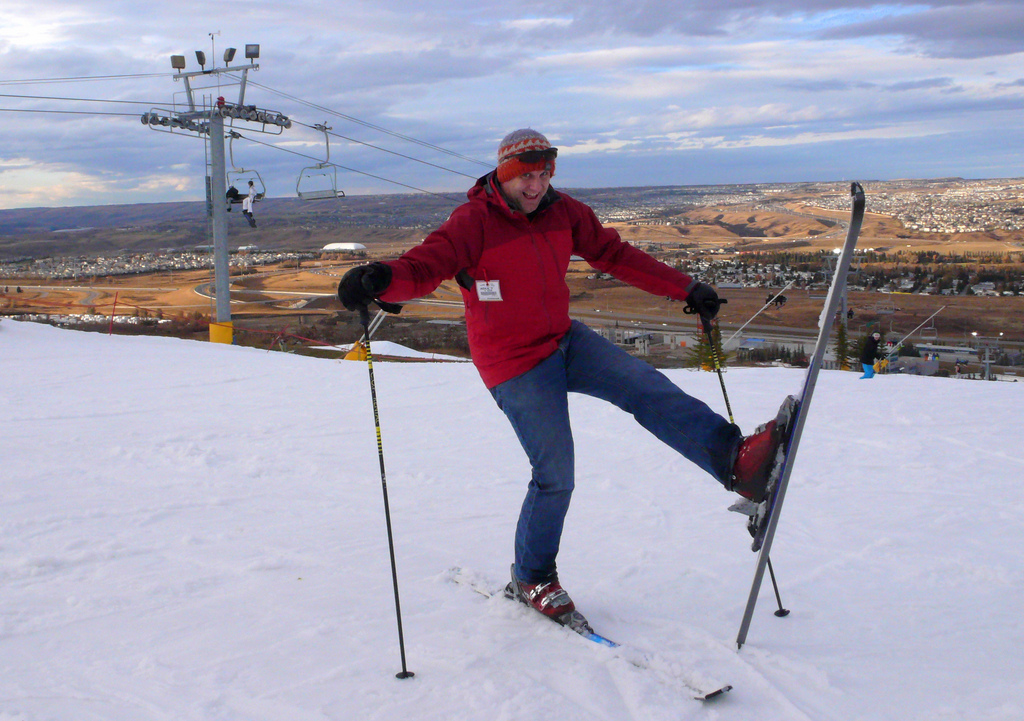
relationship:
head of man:
[394, 112, 590, 272] [394, 112, 590, 272]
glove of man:
[340, 254, 392, 309] [340, 124, 734, 631]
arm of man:
[566, 193, 702, 301] [686, 278, 725, 323]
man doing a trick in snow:
[332, 118, 803, 625] [6, 362, 1022, 717]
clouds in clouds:
[0, 0, 1024, 209] [0, 0, 1024, 209]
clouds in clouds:
[574, 71, 729, 114] [0, 0, 1024, 209]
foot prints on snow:
[139, 367, 928, 703] [6, 362, 1022, 717]